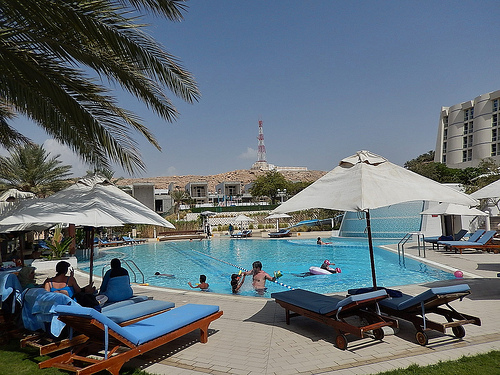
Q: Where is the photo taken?
A: At a pool.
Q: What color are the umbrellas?
A: White.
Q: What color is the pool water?
A: Blue.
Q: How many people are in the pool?
A: Six.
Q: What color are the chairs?
A: Blue.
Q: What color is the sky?
A: Blue.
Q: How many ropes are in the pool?
A: One.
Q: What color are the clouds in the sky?
A: White.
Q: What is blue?
A: Sky.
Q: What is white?
A: Umbrellas.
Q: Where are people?
A: In swimming pool.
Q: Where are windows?
A: On a building.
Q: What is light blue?
A: Water in pool.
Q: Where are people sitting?
A: On lounge chairs.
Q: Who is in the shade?
A: Two folks under the umbrellas.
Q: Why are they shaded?
A: To avoid the sun.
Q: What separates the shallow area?
A: A safety rope.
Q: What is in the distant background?
A: A tall antenna.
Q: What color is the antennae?
A: Red and white.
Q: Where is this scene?
A: At a hotel or resort.